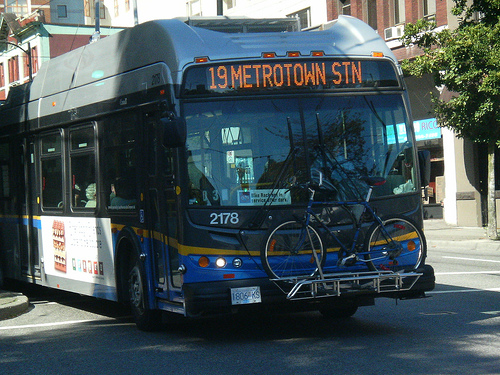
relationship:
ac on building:
[382, 23, 405, 48] [326, 0, 498, 230]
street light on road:
[4, 38, 46, 68] [29, 244, 496, 363]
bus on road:
[1, 11, 436, 337] [4, 250, 496, 374]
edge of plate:
[233, 299, 263, 309] [227, 284, 262, 306]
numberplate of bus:
[231, 286, 262, 305] [18, 24, 448, 314]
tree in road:
[401, 3, 499, 153] [4, 250, 496, 374]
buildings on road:
[3, 2, 485, 64] [396, 326, 476, 358]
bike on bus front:
[266, 159, 432, 292] [178, 13, 435, 322]